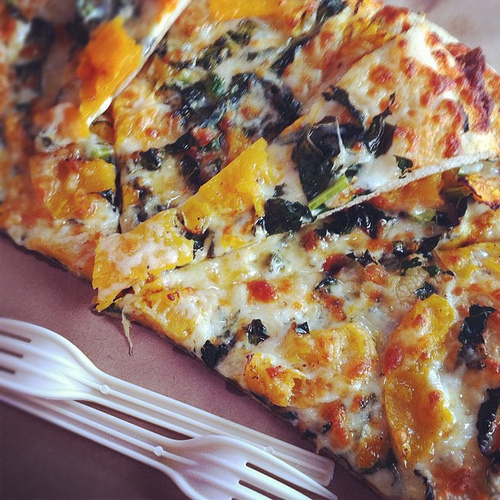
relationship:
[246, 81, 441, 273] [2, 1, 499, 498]
spinach on pizza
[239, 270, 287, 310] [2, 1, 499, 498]
tomatoes on pizza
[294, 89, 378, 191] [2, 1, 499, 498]
dark toppings on pizza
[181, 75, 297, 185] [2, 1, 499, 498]
dark toppings on pizza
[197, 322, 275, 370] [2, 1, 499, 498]
dark toppings on pizza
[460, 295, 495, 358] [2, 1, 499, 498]
dark toppings on pizza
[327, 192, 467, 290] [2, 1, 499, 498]
dark toppings on pizza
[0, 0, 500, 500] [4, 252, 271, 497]
pizza on table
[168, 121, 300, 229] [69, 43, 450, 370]
bell pepper on pizza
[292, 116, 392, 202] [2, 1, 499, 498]
spinach on pizza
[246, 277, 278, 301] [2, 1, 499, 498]
sauce on pizza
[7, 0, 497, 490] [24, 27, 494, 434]
cheese on flatbread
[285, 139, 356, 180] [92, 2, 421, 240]
spinach on pizza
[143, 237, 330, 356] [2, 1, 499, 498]
cheese on pizza